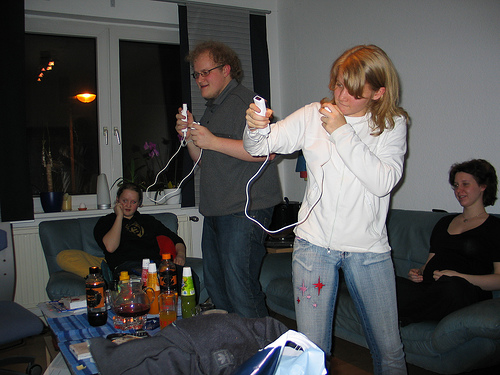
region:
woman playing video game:
[244, 44, 412, 374]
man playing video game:
[158, 38, 283, 313]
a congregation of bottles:
[73, 254, 201, 329]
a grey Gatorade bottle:
[158, 249, 175, 291]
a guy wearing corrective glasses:
[172, 33, 282, 308]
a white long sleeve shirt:
[246, 100, 408, 254]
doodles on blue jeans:
[294, 273, 331, 305]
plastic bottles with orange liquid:
[139, 259, 160, 309]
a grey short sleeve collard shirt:
[197, 84, 282, 211]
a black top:
[427, 211, 499, 289]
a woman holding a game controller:
[234, 36, 421, 174]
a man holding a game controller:
[161, 50, 255, 152]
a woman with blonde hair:
[301, 32, 400, 129]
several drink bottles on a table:
[79, 247, 191, 336]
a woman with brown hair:
[448, 152, 496, 215]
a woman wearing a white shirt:
[278, 39, 425, 271]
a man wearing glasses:
[185, 41, 230, 98]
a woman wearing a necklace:
[440, 170, 493, 252]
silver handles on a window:
[97, 112, 132, 155]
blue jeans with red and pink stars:
[283, 247, 338, 315]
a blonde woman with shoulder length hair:
[320, 40, 412, 136]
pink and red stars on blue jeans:
[293, 275, 326, 307]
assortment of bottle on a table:
[82, 252, 195, 335]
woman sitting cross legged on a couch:
[398, 159, 499, 327]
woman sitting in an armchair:
[95, 183, 186, 286]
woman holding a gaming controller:
[243, 92, 349, 238]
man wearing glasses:
[188, 66, 221, 79]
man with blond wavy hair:
[183, 35, 245, 98]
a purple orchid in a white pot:
[143, 138, 180, 208]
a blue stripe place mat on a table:
[46, 310, 131, 372]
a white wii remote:
[251, 92, 266, 122]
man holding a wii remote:
[178, 103, 203, 141]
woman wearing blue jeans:
[290, 240, 402, 369]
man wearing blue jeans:
[197, 211, 279, 311]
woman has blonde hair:
[341, 42, 396, 95]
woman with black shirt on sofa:
[430, 153, 499, 297]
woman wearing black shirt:
[437, 220, 492, 275]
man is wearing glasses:
[193, 64, 213, 82]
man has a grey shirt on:
[192, 103, 282, 218]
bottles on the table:
[79, 260, 211, 327]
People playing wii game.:
[162, 35, 434, 358]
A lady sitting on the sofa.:
[411, 158, 485, 322]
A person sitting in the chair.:
[81, 179, 183, 273]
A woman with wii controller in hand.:
[218, 87, 297, 166]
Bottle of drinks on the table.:
[84, 255, 206, 330]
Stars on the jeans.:
[293, 259, 294, 371]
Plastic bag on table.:
[248, 338, 330, 365]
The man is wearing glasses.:
[174, 57, 218, 81]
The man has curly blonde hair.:
[208, 35, 238, 66]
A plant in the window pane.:
[29, 139, 65, 216]